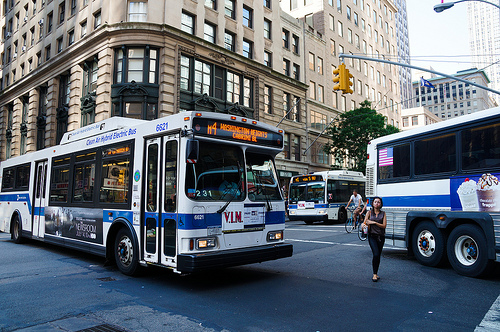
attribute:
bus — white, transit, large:
[1, 115, 298, 276]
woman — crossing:
[366, 198, 388, 283]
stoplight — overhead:
[329, 57, 354, 100]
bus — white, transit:
[364, 113, 499, 279]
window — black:
[458, 83, 463, 89]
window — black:
[446, 89, 458, 99]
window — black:
[463, 91, 471, 95]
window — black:
[419, 94, 426, 103]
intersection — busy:
[177, 157, 380, 296]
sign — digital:
[198, 113, 282, 153]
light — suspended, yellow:
[333, 69, 339, 95]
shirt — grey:
[350, 195, 362, 207]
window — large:
[113, 36, 161, 112]